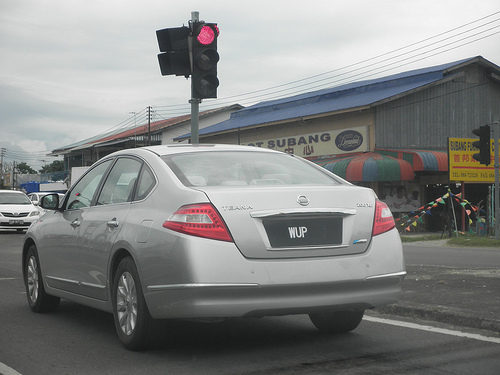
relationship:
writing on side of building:
[239, 119, 379, 167] [27, 43, 497, 251]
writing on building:
[239, 119, 379, 167] [172, 56, 497, 233]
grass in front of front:
[398, 234, 499, 246] [378, 54, 498, 229]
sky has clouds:
[0, 0, 499, 176] [13, 14, 126, 126]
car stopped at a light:
[22, 143, 405, 351] [154, 9, 223, 138]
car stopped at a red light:
[34, 147, 404, 315] [197, 25, 214, 45]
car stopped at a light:
[22, 143, 405, 351] [158, 11, 220, 142]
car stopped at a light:
[22, 143, 405, 351] [137, 9, 231, 104]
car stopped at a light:
[22, 143, 405, 351] [162, 203, 234, 243]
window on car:
[160, 143, 348, 188] [176, 146, 308, 291]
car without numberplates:
[22, 143, 405, 351] [259, 214, 349, 243]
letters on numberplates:
[281, 221, 311, 241] [262, 217, 343, 248]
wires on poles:
[202, 48, 425, 111] [153, 1, 245, 154]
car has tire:
[22, 143, 405, 351] [101, 257, 159, 366]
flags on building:
[392, 181, 489, 238] [190, 48, 499, 237]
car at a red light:
[22, 143, 405, 351] [192, 19, 220, 102]